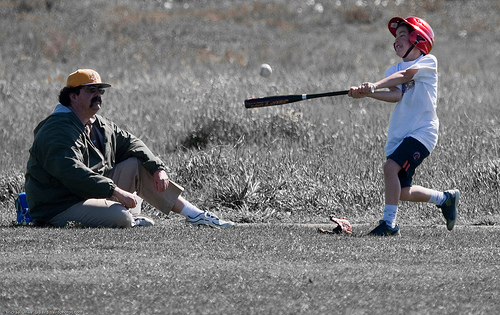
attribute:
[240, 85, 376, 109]
bat — black, metal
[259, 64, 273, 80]
baseball — white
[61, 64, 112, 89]
hat — yellow, blue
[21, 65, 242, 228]
man — sitting, older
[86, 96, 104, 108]
mustache — black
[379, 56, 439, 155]
shirt — white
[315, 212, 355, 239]
glove — brown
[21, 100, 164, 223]
jacket — green, grey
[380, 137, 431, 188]
shorts — black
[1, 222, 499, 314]
grass — gray, short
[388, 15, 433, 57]
batting helmet — red